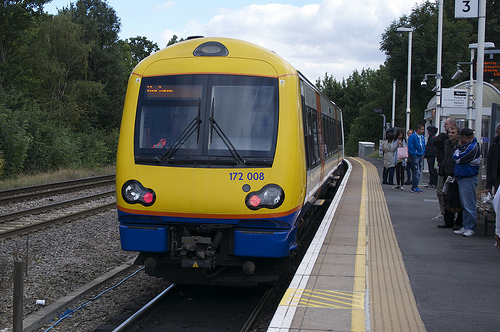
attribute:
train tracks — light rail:
[0, 167, 100, 242]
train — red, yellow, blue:
[105, 27, 330, 264]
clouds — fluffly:
[192, 11, 377, 61]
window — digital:
[134, 82, 200, 102]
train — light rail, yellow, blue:
[119, 34, 341, 284]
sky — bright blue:
[40, 3, 431, 84]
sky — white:
[140, 7, 395, 79]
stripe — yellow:
[345, 152, 377, 327]